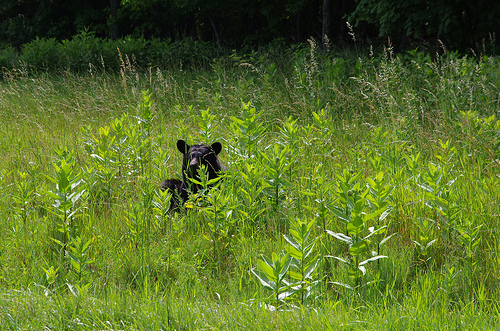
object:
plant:
[258, 131, 292, 239]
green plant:
[249, 251, 304, 312]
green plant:
[328, 194, 396, 307]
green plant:
[44, 144, 96, 293]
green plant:
[184, 156, 228, 307]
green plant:
[448, 199, 486, 280]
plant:
[249, 246, 301, 308]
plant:
[40, 147, 90, 289]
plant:
[62, 24, 100, 72]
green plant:
[316, 169, 386, 305]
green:
[138, 164, 155, 175]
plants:
[415, 130, 462, 272]